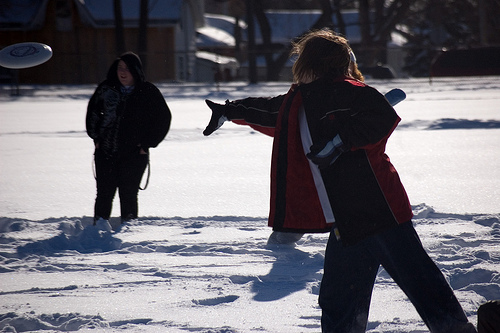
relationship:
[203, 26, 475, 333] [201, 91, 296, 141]
girl with arm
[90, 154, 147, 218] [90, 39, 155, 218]
black pants on person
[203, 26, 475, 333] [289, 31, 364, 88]
girl with brown hair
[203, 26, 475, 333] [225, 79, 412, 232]
girl wearing coat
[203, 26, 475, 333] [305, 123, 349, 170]
girl wearing gloves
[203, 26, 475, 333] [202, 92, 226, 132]
girl wearing gloves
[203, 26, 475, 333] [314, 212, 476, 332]
girl wearing pants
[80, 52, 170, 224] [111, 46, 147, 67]
person has hood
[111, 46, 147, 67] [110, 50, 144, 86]
hood on head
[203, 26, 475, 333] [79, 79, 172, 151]
girl wearing coat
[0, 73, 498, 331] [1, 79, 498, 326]
ground covered in snow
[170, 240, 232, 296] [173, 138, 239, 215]
snow on ground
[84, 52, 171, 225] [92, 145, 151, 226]
person wearing black pants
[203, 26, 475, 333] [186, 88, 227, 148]
girl wearing glove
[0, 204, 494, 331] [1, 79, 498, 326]
tracks in snow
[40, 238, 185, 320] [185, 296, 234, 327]
foot prints in snow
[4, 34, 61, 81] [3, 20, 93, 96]
frisbee with air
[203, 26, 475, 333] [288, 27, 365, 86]
girl with brown hair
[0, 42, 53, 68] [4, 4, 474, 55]
frisbee in sky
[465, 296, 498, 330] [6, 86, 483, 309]
backpack on ground